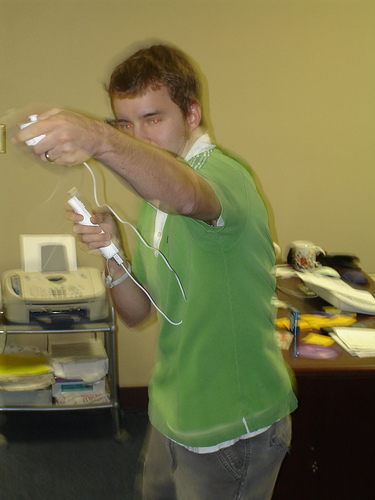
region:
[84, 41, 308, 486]
young white male with brown hair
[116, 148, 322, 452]
men's short sleeved green shirt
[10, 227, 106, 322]
old style fax machine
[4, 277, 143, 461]
silver electronics cart with wheels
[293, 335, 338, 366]
compact disc on desk top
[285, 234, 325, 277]
red and black coffee mug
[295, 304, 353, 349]
yellow post it notes on table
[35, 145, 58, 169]
men's white gold wedding band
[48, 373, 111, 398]
unopened ream of printer paper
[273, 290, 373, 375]
brown wooden desk top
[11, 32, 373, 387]
a man playing the wii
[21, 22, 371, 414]
a man holding wii remote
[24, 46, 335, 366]
a man holding white wii remote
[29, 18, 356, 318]
a man holding num chuck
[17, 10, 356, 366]
a man holding white numchuck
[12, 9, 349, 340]
man holding a wii numchuck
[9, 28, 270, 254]
a man holding a white wii numchuck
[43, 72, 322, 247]
a man wearing a ring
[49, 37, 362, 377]
a man wearing a green shirt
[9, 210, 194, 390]
a fax machine on table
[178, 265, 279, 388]
The shirt is green.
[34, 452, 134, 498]
The floor is dark blue.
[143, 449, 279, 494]
The pants are grey.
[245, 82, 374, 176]
The wall is beige.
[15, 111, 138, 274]
Man is holding a Wii controller.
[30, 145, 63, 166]
Ring on the finger.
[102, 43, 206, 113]
The hair is brown.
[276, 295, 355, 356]
Post its on the table.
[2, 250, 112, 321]
Printer on a cart.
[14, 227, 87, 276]
Paper in the printer.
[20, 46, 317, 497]
A man playing Wii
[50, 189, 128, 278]
A wii remote in the man's hand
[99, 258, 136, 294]
A wriststrap securing the remote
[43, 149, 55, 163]
A silver ring on the man's finger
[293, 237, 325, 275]
A small coffee mug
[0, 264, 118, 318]
A printer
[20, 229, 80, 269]
White paper in the printer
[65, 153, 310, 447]
A green shirt on the man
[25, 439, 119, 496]
A grey carpet under the man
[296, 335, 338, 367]
A CD on the desk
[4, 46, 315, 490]
a young man in a green shirt playing a video game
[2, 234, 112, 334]
a fax machine sitting on a silver metal stand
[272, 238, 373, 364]
a cluttered office desk behind the man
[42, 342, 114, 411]
several reams of paper on a shelf under the fax machine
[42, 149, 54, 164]
a ring on the man's finger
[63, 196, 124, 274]
a white video game controller the man is holding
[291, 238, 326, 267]
a white coffee mug with a red pattern on it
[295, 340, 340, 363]
a compact disc sitting on the corner of the desk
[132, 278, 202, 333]
the white cord from the video game controller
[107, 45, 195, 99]
the man's short brown hair